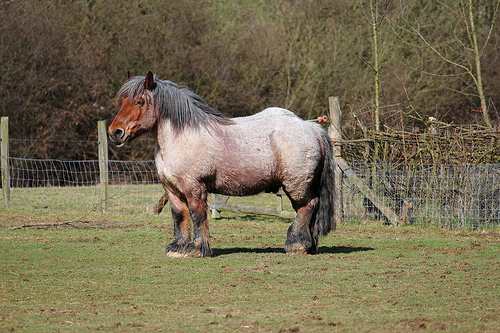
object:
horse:
[106, 70, 335, 259]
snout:
[108, 128, 124, 141]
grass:
[50, 260, 388, 309]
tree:
[0, 0, 211, 69]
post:
[97, 121, 109, 211]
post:
[327, 97, 343, 139]